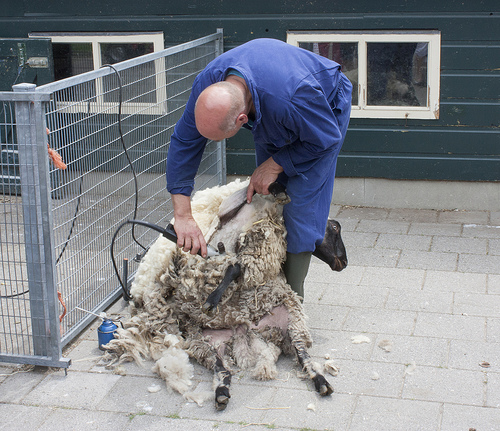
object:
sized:
[147, 214, 247, 268]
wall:
[1, 0, 499, 187]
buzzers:
[163, 217, 235, 270]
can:
[97, 318, 117, 350]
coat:
[163, 42, 351, 249]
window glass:
[367, 41, 428, 105]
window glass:
[296, 42, 358, 107]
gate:
[1, 35, 88, 137]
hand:
[160, 210, 207, 260]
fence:
[38, 24, 226, 348]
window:
[285, 32, 440, 109]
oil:
[96, 319, 117, 352]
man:
[165, 35, 353, 344]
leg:
[288, 312, 322, 397]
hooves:
[214, 388, 231, 410]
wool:
[165, 263, 207, 297]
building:
[0, 0, 500, 202]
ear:
[235, 114, 247, 125]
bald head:
[194, 81, 249, 141]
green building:
[0, 0, 499, 180]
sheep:
[105, 174, 343, 406]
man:
[169, 29, 360, 175]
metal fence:
[0, 62, 171, 365]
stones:
[383, 244, 475, 390]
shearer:
[163, 37, 354, 319]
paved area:
[324, 202, 499, 427]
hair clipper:
[164, 224, 225, 257]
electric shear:
[152, 217, 223, 264]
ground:
[359, 223, 473, 428]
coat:
[106, 169, 330, 405]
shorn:
[162, 205, 308, 360]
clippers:
[177, 240, 250, 290]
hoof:
[313, 377, 334, 395]